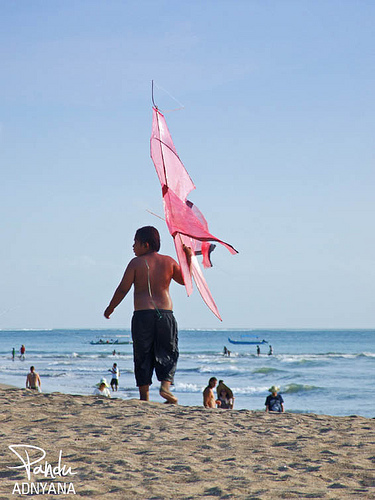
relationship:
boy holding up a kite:
[103, 224, 193, 408] [142, 77, 242, 323]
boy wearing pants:
[103, 224, 193, 408] [130, 312, 181, 386]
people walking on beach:
[200, 381, 284, 417] [13, 414, 353, 498]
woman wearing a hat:
[217, 392, 233, 410] [216, 379, 230, 395]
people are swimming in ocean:
[212, 345, 280, 356] [4, 330, 375, 409]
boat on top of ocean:
[226, 337, 268, 346] [4, 330, 375, 409]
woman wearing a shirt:
[217, 392, 233, 410] [217, 399, 227, 410]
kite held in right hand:
[142, 77, 242, 323] [179, 245, 193, 255]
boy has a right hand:
[103, 224, 193, 408] [179, 245, 193, 255]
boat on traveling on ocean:
[226, 337, 268, 346] [4, 330, 375, 409]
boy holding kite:
[103, 224, 193, 408] [142, 77, 242, 323]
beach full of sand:
[13, 414, 353, 498] [172, 474, 202, 486]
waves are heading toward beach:
[52, 357, 90, 375] [13, 414, 353, 498]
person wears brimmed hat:
[93, 373, 114, 400] [94, 377, 111, 387]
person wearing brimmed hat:
[265, 387, 286, 418] [267, 386, 279, 394]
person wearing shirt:
[265, 387, 286, 418] [263, 395, 286, 412]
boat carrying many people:
[87, 335, 131, 349] [98, 340, 128, 344]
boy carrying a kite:
[103, 224, 193, 408] [142, 77, 242, 323]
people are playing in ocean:
[212, 345, 280, 356] [4, 330, 375, 409]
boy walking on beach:
[103, 224, 193, 408] [13, 414, 353, 498]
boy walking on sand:
[103, 224, 193, 408] [172, 474, 202, 486]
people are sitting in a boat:
[98, 340, 128, 344] [87, 335, 131, 349]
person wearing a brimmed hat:
[265, 387, 286, 418] [267, 386, 279, 394]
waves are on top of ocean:
[52, 357, 90, 375] [4, 330, 375, 409]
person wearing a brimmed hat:
[93, 373, 114, 400] [94, 377, 111, 387]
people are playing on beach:
[200, 381, 284, 417] [13, 414, 353, 498]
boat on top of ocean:
[87, 335, 131, 349] [4, 330, 375, 409]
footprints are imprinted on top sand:
[98, 454, 192, 486] [172, 474, 202, 486]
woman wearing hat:
[217, 392, 233, 410] [216, 379, 230, 395]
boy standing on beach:
[103, 224, 193, 408] [13, 414, 353, 498]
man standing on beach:
[23, 365, 43, 394] [13, 414, 353, 498]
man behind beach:
[265, 387, 286, 418] [13, 414, 353, 498]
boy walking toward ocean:
[103, 224, 193, 408] [4, 330, 375, 409]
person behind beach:
[93, 373, 114, 400] [13, 414, 353, 498]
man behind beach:
[23, 365, 43, 394] [13, 414, 353, 498]